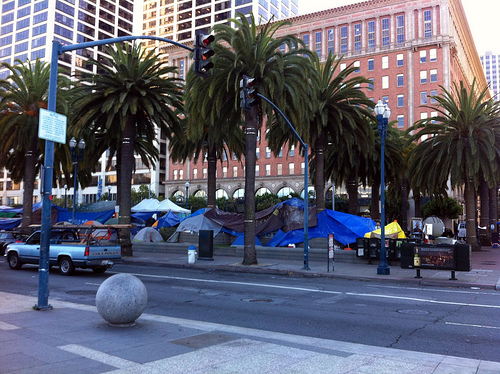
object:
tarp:
[1, 198, 117, 228]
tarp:
[134, 195, 191, 231]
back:
[85, 244, 122, 259]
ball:
[92, 269, 150, 330]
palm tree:
[185, 14, 318, 267]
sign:
[37, 106, 67, 144]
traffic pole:
[36, 40, 58, 313]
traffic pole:
[301, 137, 310, 271]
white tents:
[156, 199, 188, 211]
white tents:
[131, 197, 158, 212]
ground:
[0, 254, 500, 373]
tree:
[360, 120, 416, 222]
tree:
[271, 50, 369, 216]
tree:
[68, 35, 184, 255]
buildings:
[0, 0, 309, 201]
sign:
[328, 235, 335, 259]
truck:
[4, 227, 121, 273]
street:
[1, 268, 500, 358]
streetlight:
[383, 103, 392, 120]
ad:
[402, 244, 470, 269]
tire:
[60, 256, 71, 275]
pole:
[375, 137, 391, 277]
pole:
[38, 53, 56, 306]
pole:
[70, 157, 79, 220]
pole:
[182, 48, 190, 207]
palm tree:
[400, 77, 497, 251]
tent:
[365, 220, 404, 238]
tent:
[230, 195, 374, 248]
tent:
[170, 205, 238, 244]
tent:
[131, 227, 162, 242]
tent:
[152, 209, 187, 231]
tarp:
[208, 196, 381, 247]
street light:
[374, 99, 386, 119]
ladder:
[38, 223, 137, 244]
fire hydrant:
[186, 243, 198, 265]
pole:
[298, 144, 314, 269]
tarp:
[364, 218, 406, 241]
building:
[151, 0, 496, 245]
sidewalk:
[2, 297, 497, 373]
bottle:
[412, 252, 423, 267]